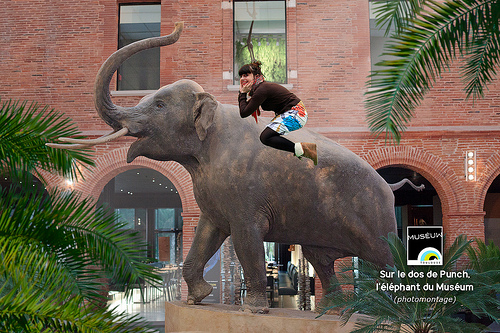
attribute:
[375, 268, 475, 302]
writing — white, spanish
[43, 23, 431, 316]
statue — elephant, stone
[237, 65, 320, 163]
woman — posing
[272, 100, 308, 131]
shorts — multicolored, white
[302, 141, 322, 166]
boots — furry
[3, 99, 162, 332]
tree — large, green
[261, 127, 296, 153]
leggings — black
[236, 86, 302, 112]
shirt — long sleeve, brown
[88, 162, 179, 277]
doorway — arched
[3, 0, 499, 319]
building — brick, multicolor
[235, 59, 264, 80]
hair — pulled back, brown, up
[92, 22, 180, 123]
trunk — raised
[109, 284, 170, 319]
floor — tile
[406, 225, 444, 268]
sign — advertisement, logo